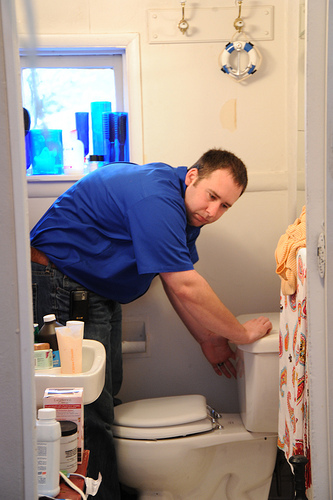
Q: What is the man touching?
A: Toilet tank.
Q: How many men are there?
A: One.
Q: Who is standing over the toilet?
A: The man.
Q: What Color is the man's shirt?
A: Blue.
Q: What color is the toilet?
A: White.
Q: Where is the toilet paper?
A: On the wall.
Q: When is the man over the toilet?
A: Daytime.